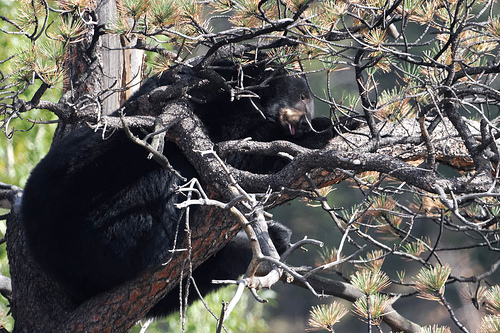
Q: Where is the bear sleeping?
A: In a tree.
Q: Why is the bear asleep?
A: The bear is tired.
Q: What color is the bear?
A: Black.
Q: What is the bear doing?
A: The bear is sleeping.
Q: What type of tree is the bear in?
A: A pine tree.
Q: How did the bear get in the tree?
A: The bear climbed.